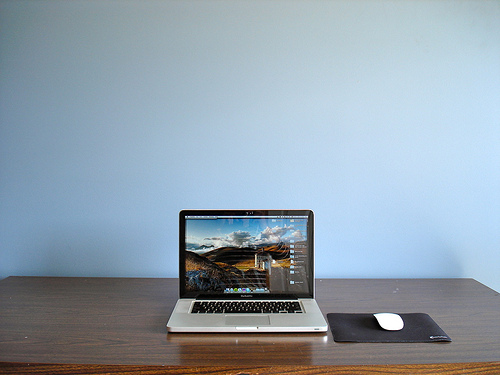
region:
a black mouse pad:
[326, 308, 454, 353]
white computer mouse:
[371, 308, 419, 330]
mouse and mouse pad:
[328, 306, 460, 350]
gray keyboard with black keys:
[168, 298, 335, 340]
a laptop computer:
[178, 210, 338, 347]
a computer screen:
[174, 206, 332, 296]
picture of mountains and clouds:
[186, 216, 315, 293]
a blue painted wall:
[129, 185, 273, 257]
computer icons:
[286, 218, 313, 288]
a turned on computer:
[172, 200, 339, 352]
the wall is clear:
[50, 54, 365, 191]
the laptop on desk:
[160, 174, 445, 374]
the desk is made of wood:
[86, 256, 124, 367]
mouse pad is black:
[322, 298, 464, 337]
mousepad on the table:
[323, 298, 472, 351]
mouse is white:
[361, 300, 431, 340]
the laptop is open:
[145, 196, 384, 359]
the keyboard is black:
[190, 297, 325, 326]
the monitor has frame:
[159, 202, 334, 303]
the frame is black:
[156, 206, 341, 298]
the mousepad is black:
[355, 314, 375, 372]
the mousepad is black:
[333, 330, 353, 347]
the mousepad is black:
[352, 343, 366, 350]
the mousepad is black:
[346, 319, 361, 346]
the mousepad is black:
[350, 314, 367, 344]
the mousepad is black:
[342, 290, 359, 352]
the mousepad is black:
[357, 327, 371, 348]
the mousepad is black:
[339, 316, 354, 336]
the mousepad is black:
[343, 308, 353, 332]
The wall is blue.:
[84, 49, 426, 120]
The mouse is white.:
[371, 310, 398, 333]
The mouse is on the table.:
[364, 305, 407, 340]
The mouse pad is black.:
[322, 299, 454, 357]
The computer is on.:
[150, 207, 342, 367]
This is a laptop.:
[161, 199, 326, 354]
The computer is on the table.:
[146, 197, 346, 369]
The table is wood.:
[20, 283, 137, 355]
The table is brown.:
[25, 279, 158, 350]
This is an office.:
[18, 28, 475, 373]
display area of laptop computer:
[180, 210, 312, 297]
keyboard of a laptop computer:
[190, 297, 303, 314]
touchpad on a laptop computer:
[220, 313, 273, 330]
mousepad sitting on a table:
[325, 309, 452, 346]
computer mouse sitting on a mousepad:
[367, 304, 412, 337]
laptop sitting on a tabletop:
[165, 200, 332, 334]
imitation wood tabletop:
[2, 270, 499, 373]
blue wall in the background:
[13, 0, 489, 207]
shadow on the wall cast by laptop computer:
[24, 196, 165, 276]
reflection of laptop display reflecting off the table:
[170, 334, 320, 369]